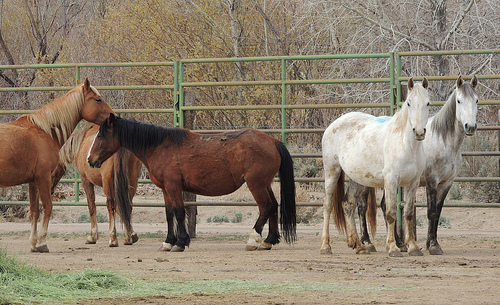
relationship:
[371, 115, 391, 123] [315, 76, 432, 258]
mark painted on horse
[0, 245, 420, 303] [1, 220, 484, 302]
grass thrown on ground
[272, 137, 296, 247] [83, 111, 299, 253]
tail belonging to horse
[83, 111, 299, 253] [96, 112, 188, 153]
horse growing mane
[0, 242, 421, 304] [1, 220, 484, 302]
grass scattered on ground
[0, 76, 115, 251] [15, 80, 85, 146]
horse growing mane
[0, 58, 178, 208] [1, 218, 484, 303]
panel bordering corral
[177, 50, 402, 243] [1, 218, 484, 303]
panel bordering corral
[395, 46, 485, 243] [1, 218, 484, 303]
panel bordering corral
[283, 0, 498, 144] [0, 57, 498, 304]
tree behind corral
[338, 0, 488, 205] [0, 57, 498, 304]
tree behind corral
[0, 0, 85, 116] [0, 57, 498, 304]
tree behind corral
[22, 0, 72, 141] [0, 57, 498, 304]
tree behind corral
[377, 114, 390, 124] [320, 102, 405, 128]
mark on back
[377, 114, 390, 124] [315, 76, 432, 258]
mark on horse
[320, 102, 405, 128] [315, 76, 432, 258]
back on horse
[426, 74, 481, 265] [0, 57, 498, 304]
horse standing in a corral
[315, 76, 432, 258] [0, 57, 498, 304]
horse standing in a corral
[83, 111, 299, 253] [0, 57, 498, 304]
horse standing in a corral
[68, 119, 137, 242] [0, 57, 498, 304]
horse standing in a corral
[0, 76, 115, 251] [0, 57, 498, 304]
horse standing in a corral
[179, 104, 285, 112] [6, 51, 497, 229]
pole on fence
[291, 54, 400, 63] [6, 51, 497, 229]
pole on fence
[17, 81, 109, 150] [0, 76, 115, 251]
mane on horse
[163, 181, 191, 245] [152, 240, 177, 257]
leg with hooves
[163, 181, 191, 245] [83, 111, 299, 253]
leg of a horse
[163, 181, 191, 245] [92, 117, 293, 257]
leg of a horse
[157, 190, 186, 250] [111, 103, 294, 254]
leg of a horse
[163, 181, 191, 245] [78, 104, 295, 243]
leg of a horse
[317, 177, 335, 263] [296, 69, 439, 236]
leg of a horse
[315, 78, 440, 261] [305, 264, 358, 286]
horse on the ground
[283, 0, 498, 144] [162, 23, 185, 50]
tree has leaves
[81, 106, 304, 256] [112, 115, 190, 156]
horse has mane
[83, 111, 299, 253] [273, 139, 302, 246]
horse has tail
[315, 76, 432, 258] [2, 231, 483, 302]
horse on dirt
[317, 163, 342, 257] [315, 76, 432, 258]
leg of horse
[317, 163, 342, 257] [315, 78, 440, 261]
leg of horse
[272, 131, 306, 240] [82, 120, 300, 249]
tail of horse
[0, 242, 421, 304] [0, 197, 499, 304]
grass on floor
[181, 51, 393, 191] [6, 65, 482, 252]
poles next to horse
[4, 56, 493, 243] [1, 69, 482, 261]
fence near horses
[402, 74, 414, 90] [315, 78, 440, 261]
ear on horse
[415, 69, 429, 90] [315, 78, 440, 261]
ear on horse